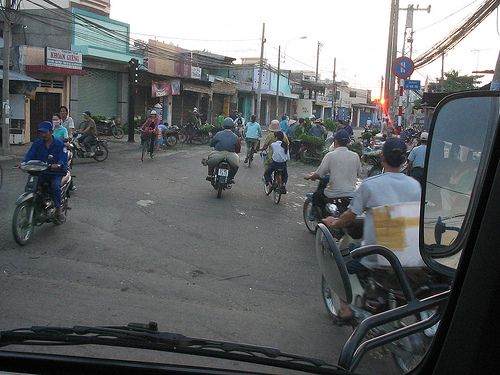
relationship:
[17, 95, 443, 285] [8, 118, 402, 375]
people in street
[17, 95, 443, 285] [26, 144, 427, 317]
people on mopeds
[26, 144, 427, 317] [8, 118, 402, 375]
mopeds in street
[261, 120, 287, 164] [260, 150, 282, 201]
person on a bicycle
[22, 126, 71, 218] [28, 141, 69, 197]
man wearing blue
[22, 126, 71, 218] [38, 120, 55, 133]
man wearing hat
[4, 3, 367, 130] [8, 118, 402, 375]
storefronts on street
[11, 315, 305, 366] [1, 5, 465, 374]
wiper on window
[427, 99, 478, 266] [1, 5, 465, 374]
mirror on window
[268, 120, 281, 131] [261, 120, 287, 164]
hat on person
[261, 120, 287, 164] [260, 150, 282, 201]
person riding on a bicycle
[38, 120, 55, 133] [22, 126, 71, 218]
hat on man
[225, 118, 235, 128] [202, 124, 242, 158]
helmet on bicyclist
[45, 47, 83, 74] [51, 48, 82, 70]
sign with letters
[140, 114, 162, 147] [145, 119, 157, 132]
woman wearing shirt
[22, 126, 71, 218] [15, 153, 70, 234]
man riding a moped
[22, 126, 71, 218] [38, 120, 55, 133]
man wearing a hat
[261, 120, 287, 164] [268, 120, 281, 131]
person wearing hat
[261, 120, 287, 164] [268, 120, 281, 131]
person wearing a hat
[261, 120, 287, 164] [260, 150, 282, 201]
person riding a bicycle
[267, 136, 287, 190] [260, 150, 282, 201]
person riding a bicycle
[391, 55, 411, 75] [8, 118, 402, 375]
sign on street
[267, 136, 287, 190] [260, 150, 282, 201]
person on bicycle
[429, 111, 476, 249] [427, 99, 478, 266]
reflection in mirror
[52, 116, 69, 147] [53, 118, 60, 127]
woman wearing a mask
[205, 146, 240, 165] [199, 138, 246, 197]
luggage on moped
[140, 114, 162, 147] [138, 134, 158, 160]
woman riding a bicycle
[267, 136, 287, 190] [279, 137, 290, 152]
person with a ponytail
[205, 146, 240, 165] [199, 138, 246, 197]
luggage on a moped